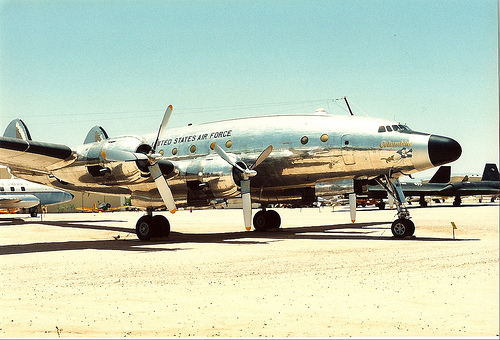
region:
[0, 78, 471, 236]
United States Air Force plane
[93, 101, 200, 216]
Propellers on a United States Air Force Plane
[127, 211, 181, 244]
Airplane wheels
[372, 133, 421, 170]
Graphics on the side of a plane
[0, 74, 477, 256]
Antique United States Air Force Plane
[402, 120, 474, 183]
Airplane nose cone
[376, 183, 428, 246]
front landing gear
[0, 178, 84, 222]
Retired Air Force One plane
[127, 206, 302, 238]
landing gear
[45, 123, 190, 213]
airplane engine with propeller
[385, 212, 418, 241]
The black front wheel on the airplane.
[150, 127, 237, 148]
United States Airforce writing on the plane.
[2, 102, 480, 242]
A silver plane on the runway.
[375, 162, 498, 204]
A black jet in the background.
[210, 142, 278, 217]
The front propeller on the right side of the plane.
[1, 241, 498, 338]
The dirt on the ground that makes the runway.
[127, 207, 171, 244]
The back wheel on the planes right side.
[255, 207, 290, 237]
The back wheel on the planes left side.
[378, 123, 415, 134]
The pilots window on the plane.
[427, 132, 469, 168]
The black nose of the plane.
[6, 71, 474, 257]
Old airplane is outdoors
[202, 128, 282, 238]
Small propeller of plane on the side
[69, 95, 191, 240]
Big propeller of plane on the side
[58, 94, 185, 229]
Propeller of engine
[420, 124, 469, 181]
Tip of plane is black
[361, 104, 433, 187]
Cockpit of plane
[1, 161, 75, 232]
Plane on background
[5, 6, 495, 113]
Sky is blue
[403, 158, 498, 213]
Black plane in the background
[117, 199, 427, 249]
Black wheels of plane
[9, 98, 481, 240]
Air plane on ground.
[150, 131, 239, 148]
United States Air Force on side of plane.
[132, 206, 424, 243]
Wheels of plane securely stopped.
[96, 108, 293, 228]
Propellers on side of plane.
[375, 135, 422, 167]
Logo of pilot on side of plane.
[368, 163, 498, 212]
Black airplane in background.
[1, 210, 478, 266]
Shadow of plane on the ground.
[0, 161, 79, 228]
Partial airplane in background.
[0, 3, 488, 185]
Blue skies in background.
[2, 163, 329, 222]
Buildings in the background.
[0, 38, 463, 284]
A picture of an airplane.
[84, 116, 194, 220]
Outside right propeller.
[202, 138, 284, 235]
Inside right propeller.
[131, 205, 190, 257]
Back right side wheels.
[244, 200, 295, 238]
Back left side wheel.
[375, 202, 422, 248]
Front wheel.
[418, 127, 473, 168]
Black nose of airplane.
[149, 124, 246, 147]
The words UNITED STATES AIR FORCE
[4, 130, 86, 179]
Right wing of airplane with black edge.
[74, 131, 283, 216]
Two engines on right side.